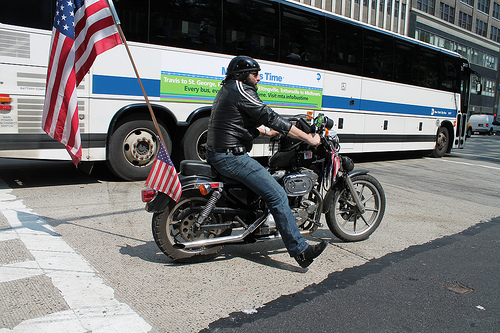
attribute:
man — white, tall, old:
[203, 41, 337, 272]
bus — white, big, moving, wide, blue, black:
[0, 2, 477, 163]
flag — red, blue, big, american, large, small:
[39, 1, 179, 203]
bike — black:
[135, 114, 381, 262]